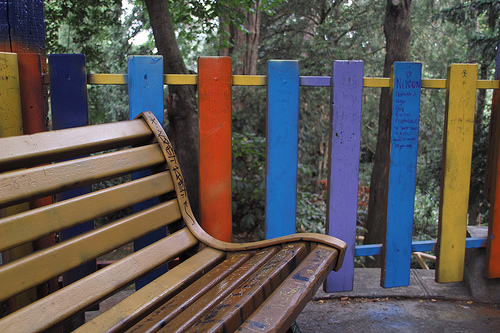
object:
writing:
[391, 142, 414, 150]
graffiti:
[389, 64, 419, 153]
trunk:
[364, 0, 416, 269]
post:
[436, 59, 478, 285]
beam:
[43, 71, 497, 89]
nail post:
[447, 244, 457, 249]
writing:
[145, 112, 204, 227]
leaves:
[61, 14, 94, 42]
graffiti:
[230, 242, 334, 333]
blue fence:
[381, 61, 421, 290]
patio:
[0, 0, 499, 333]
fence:
[46, 51, 499, 313]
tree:
[45, 0, 499, 268]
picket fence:
[44, 47, 500, 314]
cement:
[347, 297, 433, 323]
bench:
[0, 109, 351, 332]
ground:
[282, 264, 499, 333]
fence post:
[267, 58, 302, 240]